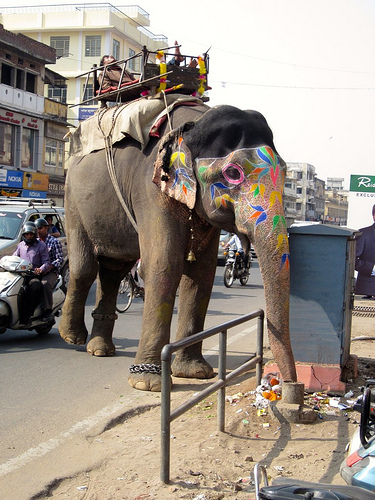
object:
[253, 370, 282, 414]
pile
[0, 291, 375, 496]
ground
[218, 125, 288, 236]
face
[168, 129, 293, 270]
paint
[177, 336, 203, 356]
ankle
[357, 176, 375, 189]
sign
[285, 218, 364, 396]
post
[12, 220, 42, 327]
man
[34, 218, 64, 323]
man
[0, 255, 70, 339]
bike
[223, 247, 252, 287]
bike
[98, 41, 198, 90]
man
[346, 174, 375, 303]
sign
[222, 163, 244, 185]
pink eye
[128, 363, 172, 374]
chain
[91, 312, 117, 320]
chain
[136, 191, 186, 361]
leg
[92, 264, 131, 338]
leg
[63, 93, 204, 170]
sheet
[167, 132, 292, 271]
colors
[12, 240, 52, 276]
shirt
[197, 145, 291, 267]
painted face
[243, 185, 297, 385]
trunk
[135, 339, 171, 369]
ankle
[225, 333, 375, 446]
trash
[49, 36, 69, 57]
window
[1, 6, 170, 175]
building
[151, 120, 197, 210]
ear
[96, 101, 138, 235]
rope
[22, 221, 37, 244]
helmet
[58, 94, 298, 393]
elephant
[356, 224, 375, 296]
top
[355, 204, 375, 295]
man's picture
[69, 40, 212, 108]
carriage